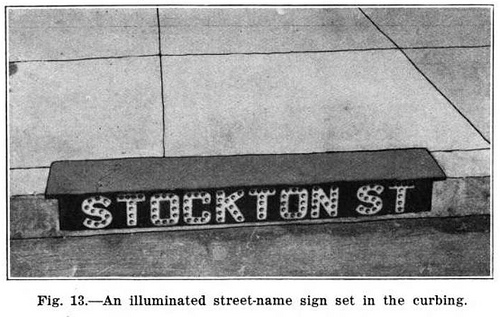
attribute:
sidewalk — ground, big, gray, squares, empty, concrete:
[10, 5, 492, 241]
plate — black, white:
[46, 147, 444, 233]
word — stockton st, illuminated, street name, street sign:
[83, 182, 417, 229]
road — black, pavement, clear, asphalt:
[10, 212, 490, 279]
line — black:
[8, 43, 490, 65]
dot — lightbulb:
[98, 207, 107, 215]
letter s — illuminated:
[81, 194, 113, 230]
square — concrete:
[159, 46, 491, 159]